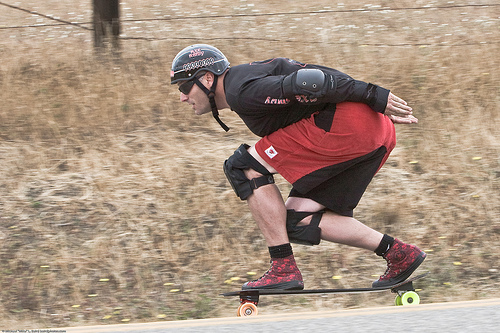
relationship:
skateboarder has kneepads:
[144, 52, 378, 198] [212, 140, 291, 193]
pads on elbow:
[283, 70, 322, 101] [257, 51, 353, 114]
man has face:
[174, 85, 430, 203] [160, 68, 204, 110]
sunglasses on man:
[160, 68, 204, 110] [174, 85, 430, 203]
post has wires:
[86, 8, 126, 60] [8, 3, 93, 43]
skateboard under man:
[227, 288, 282, 319] [174, 85, 430, 203]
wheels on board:
[240, 294, 426, 313] [220, 243, 395, 314]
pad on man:
[281, 218, 319, 238] [174, 85, 430, 203]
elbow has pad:
[257, 51, 353, 114] [281, 218, 319, 238]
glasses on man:
[156, 77, 223, 104] [174, 85, 430, 203]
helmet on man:
[165, 41, 274, 95] [174, 85, 430, 203]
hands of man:
[345, 87, 454, 137] [174, 85, 430, 203]